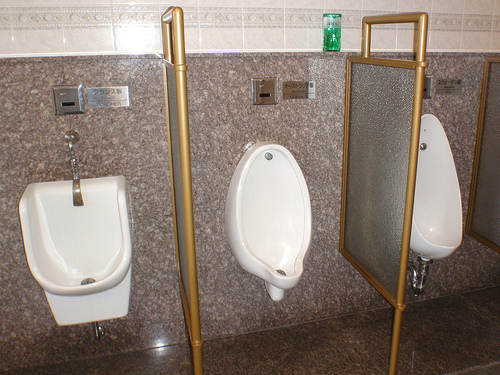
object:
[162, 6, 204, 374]
divider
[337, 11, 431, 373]
divider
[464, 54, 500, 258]
divider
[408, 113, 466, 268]
urinal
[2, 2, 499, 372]
wall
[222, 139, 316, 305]
urinal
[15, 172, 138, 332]
urinal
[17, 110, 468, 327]
three urinals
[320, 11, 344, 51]
air freshener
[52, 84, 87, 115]
mechanism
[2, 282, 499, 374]
floor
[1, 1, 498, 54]
tile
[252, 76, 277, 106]
mechanism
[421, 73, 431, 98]
mechanism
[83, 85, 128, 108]
metal plate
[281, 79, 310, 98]
metal plate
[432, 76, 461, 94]
metal plate